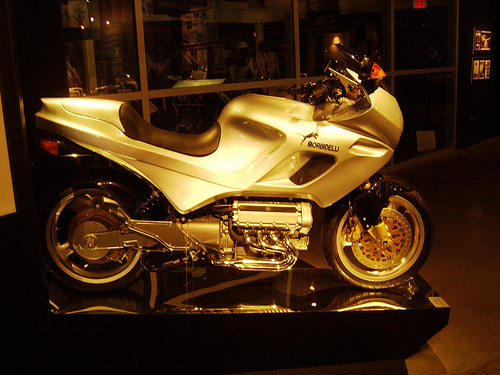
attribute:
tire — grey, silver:
[320, 190, 434, 290]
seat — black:
[120, 102, 220, 156]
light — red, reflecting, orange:
[43, 141, 61, 158]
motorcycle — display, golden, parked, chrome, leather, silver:
[32, 44, 435, 293]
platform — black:
[43, 261, 449, 363]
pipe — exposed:
[232, 259, 295, 274]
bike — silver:
[32, 44, 434, 287]